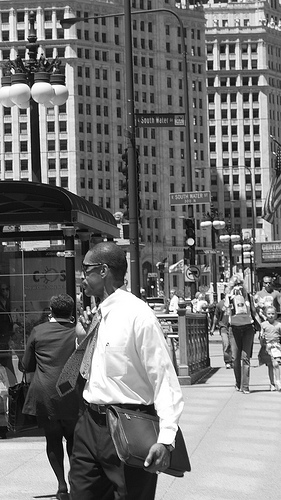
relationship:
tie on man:
[54, 311, 103, 402] [50, 244, 193, 498]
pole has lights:
[24, 13, 49, 196] [2, 59, 74, 110]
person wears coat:
[16, 291, 106, 499] [14, 320, 88, 422]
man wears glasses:
[50, 244, 193, 498] [76, 261, 104, 273]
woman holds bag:
[220, 274, 264, 397] [228, 293, 247, 318]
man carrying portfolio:
[50, 244, 193, 498] [103, 403, 194, 480]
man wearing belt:
[50, 244, 193, 498] [81, 397, 155, 418]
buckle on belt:
[96, 403, 114, 417] [81, 397, 155, 418]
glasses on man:
[76, 261, 104, 273] [50, 244, 193, 498]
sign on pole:
[181, 267, 203, 288] [171, 13, 207, 331]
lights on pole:
[2, 59, 74, 110] [24, 13, 49, 196]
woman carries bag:
[220, 274, 264, 397] [228, 293, 247, 318]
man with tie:
[50, 244, 193, 498] [54, 311, 103, 402]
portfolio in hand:
[103, 403, 194, 480] [140, 444, 174, 481]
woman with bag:
[220, 274, 264, 397] [228, 293, 247, 318]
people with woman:
[257, 305, 280, 392] [220, 274, 264, 397]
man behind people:
[251, 274, 280, 325] [257, 305, 280, 392]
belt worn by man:
[81, 397, 155, 418] [50, 244, 193, 498]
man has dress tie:
[50, 244, 193, 498] [54, 311, 103, 402]